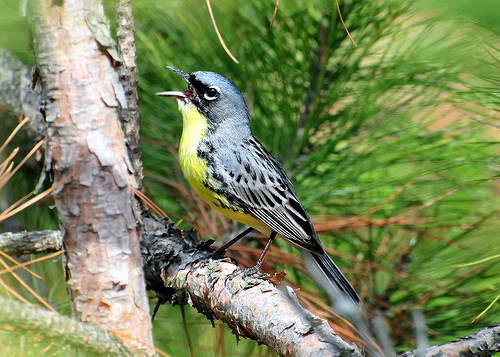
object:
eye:
[199, 84, 222, 105]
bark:
[83, 11, 126, 73]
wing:
[196, 141, 321, 254]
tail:
[299, 249, 364, 304]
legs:
[226, 230, 276, 282]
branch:
[142, 214, 499, 357]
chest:
[178, 120, 216, 211]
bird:
[156, 65, 362, 307]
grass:
[329, 133, 500, 332]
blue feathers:
[222, 144, 251, 177]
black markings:
[258, 170, 267, 186]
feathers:
[284, 202, 309, 224]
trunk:
[32, 0, 152, 349]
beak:
[155, 66, 191, 99]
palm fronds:
[359, 155, 498, 194]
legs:
[187, 225, 254, 266]